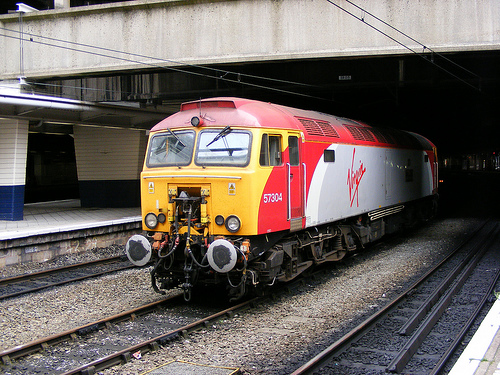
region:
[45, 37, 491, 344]
train emerging from tunnel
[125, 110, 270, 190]
two windows on front of train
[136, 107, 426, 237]
white train with red and yellow accents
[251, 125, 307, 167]
two windows on side of train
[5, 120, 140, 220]
wide supporting columns in white and blue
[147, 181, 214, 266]
opening in front of train with curled tubing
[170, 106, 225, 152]
light centered above two windows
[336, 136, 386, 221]
company name in red on side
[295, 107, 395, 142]
vents on the side of train roof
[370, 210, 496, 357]
rails laying within tracks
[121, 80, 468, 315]
Red, yellow and grey train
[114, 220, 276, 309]
Grey front bumper of a train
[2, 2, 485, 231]
A street overpass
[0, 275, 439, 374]
Train tracks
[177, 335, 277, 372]
Grey gravel in between train tracks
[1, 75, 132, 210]
White and blue support beams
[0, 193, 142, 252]
White tile walkway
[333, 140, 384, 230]
Virgin Mobile logo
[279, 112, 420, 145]
train roof ventilation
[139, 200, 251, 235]
Headlights on the front of a train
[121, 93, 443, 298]
a long colorful train on the center track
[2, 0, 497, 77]
the bridge above the train tracks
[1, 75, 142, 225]
the building next to the train tracks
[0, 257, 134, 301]
a train track next to the building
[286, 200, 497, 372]
another track by the other platform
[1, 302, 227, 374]
the center track the train is sitting on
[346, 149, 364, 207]
the logo on the side of the train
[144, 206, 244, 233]
the lights on the front of the train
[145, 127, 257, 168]
the front windows on the train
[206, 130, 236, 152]
the windshield wiper on the window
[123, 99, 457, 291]
the train is red, yellow and white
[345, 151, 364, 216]
Virgin is written on the train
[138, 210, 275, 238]
lights on the train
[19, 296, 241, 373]
set of train tracks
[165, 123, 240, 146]
windshield wipers for the train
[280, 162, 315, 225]
railing to help get on the train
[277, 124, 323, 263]
the door to the train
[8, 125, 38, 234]
divider is blue and white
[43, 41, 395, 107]
power lines for the train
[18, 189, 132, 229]
the platform for the people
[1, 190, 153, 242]
platform at a train station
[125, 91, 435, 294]
engine of a train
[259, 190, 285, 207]
the number of the train engine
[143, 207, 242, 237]
headlights in front of a train engine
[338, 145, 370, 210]
an advertisement on the side of a train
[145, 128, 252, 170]
front windows on a train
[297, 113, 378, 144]
vents on the side of a train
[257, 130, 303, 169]
side windows on the engine of a train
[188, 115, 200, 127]
light on the top of the engine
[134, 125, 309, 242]
yellow portion of the engine